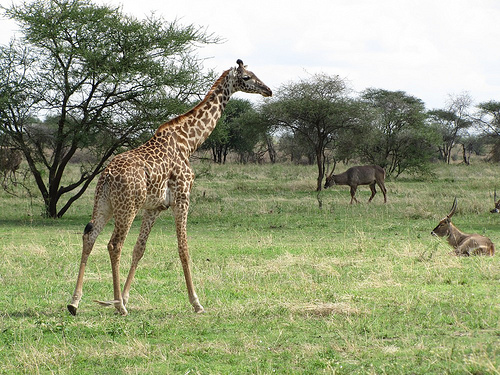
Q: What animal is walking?
A: Giraffe.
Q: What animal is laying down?
A: Antelope.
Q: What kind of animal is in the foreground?
A: Giraffe.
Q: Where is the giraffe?
A: Field.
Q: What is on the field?
A: Grass.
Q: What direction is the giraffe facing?
A: Right.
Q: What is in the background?
A: Animals and trees.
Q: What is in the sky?
A: Clouds.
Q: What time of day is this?
A: Daylight hours.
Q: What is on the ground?
A: Green and yellow grass.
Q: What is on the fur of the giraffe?
A: Brown spots.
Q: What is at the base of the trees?
A: Tree trunk.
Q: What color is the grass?
A: Green.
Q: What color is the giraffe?
A: Brown and white.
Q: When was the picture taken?
A: Daytime.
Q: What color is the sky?
A: Gray.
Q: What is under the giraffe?
A: Grass.